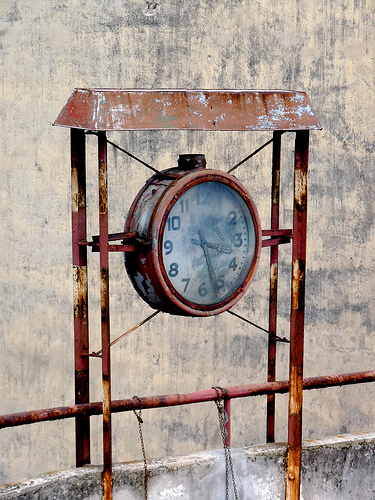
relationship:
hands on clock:
[189, 225, 238, 284] [125, 164, 272, 314]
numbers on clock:
[181, 275, 194, 292] [148, 172, 259, 313]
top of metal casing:
[49, 85, 323, 132] [50, 87, 322, 498]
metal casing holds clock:
[50, 87, 322, 498] [156, 175, 260, 312]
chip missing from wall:
[141, 1, 162, 16] [0, 0, 375, 499]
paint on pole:
[74, 265, 88, 321] [70, 130, 91, 468]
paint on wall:
[87, 449, 373, 498] [4, 430, 373, 498]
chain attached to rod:
[127, 392, 152, 498] [0, 368, 375, 432]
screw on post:
[285, 470, 297, 483] [284, 131, 309, 498]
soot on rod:
[102, 396, 155, 409] [0, 368, 375, 432]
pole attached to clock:
[87, 306, 175, 362] [136, 167, 258, 314]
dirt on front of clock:
[196, 191, 239, 281] [136, 167, 258, 314]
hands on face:
[189, 224, 234, 292] [164, 184, 254, 303]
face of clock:
[164, 184, 254, 303] [156, 175, 260, 312]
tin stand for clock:
[53, 81, 312, 498] [156, 175, 260, 312]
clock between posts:
[156, 175, 260, 312] [64, 132, 314, 462]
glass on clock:
[164, 184, 252, 308] [156, 175, 260, 312]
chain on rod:
[132, 392, 152, 499] [0, 368, 375, 432]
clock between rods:
[119, 148, 273, 323] [108, 135, 153, 172]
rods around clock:
[108, 135, 153, 172] [119, 148, 273, 323]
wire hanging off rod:
[132, 417, 245, 498] [111, 379, 285, 413]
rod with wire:
[111, 379, 285, 413] [132, 417, 245, 498]